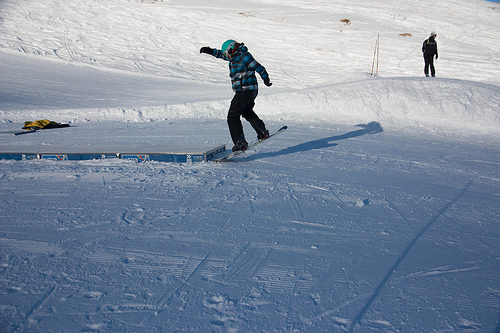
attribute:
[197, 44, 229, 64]
arm —  the   left 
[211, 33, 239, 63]
helmet — blue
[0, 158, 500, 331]
snow —  white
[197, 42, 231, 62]
arm —  the right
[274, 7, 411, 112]
snow — white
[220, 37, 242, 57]
helmet —  blue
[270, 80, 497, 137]
snow —  white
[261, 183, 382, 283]
snow — white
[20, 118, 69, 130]
coat — abandon, yellow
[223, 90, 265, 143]
pants — black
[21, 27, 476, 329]
snow — white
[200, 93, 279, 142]
pants — black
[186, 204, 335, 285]
snow — bluish white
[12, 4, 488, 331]
snow — white,  white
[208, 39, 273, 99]
coat — blue, purple, black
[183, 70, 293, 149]
person — playing